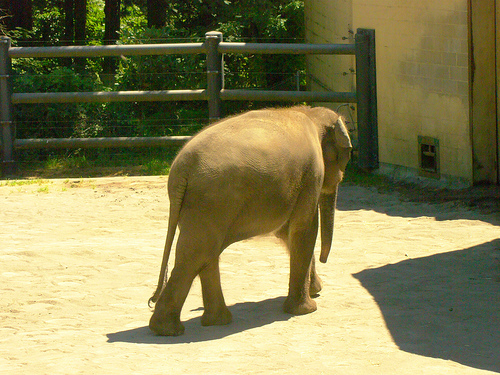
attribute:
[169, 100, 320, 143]
hairs — fuzzy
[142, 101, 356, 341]
elephant — tan, young, zoo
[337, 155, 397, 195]
grass — green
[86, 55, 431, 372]
elephant — baby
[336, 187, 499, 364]
shadows — curved, angled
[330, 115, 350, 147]
ear — curled back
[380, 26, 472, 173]
bricks — painted, yellow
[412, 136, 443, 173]
window — tiny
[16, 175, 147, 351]
ground — flat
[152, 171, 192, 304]
tail — long